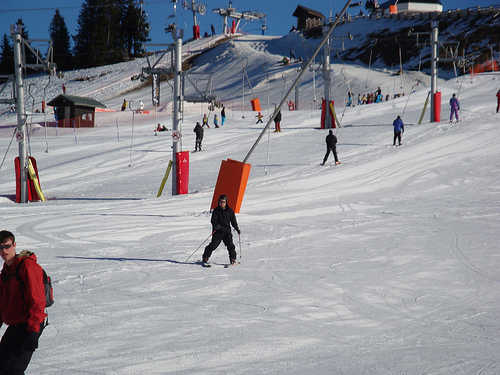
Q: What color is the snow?
A: White.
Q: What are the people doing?
A: Skiing.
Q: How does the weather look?
A: Cold.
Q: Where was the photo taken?
A: Colorado.